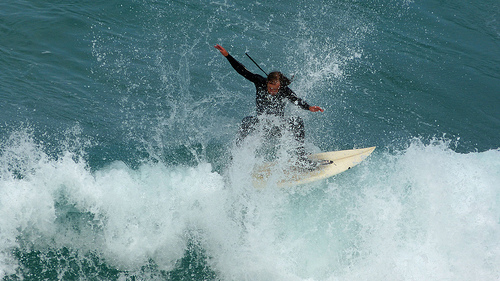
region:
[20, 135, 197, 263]
white waves crashing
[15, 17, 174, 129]
calm light blue water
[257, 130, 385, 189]
bright white surfboard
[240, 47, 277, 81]
string coming off of a wetsuit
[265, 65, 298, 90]
a persons wet hair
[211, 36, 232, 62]
the hand of a surfer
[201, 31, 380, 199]
a person surfing on waves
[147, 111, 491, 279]
high white wave the surfer is riding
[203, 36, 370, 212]
balancing on a surfoard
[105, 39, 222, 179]
white mist from the water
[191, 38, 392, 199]
person sufring a wave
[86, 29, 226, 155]
droplets of water splashing up from the wave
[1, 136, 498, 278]
large white wave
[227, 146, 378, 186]
thin cream surboard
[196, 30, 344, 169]
person in a black wetsuit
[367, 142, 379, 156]
pointed tip of the surfboard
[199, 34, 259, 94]
arm extended up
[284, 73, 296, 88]
hair blowing in the wind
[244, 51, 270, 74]
thin and black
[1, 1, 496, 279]
body of water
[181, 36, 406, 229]
person surfing some waves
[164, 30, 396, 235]
person surfing some good waves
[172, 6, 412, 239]
person surfing some big waves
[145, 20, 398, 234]
person surfing some nice waves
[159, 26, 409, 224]
person surfing some huge waves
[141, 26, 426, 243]
person surfing some awesome waves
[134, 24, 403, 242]
person surfing some ocean waves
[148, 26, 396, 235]
person surfing great waves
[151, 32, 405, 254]
person surfing huge waves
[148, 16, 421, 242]
person surfing beautiful waves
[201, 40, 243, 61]
mans hand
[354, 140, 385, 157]
tip of the board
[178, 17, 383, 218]
man of the surfboard is on a wave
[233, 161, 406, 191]
a white surfboard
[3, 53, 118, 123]
blue/green water in the ocean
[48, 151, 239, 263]
white foam from the ocean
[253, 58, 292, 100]
the mans head is wet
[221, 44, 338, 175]
a black wetsuit on the man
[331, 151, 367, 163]
a stripe on the surfboard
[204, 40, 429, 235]
the man is balancing on the surfboard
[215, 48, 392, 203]
a person surfing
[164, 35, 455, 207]
a person riding a wave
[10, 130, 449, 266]
the crest of a wave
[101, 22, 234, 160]
white sea spray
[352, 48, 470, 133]
blue ocean water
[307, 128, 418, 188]
the front end of a beige surfboard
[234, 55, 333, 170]
a person wearing a black wetsuit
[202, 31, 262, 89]
a surfer's arm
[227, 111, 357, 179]
the legs of a surfer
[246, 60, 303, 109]
a surfer's head